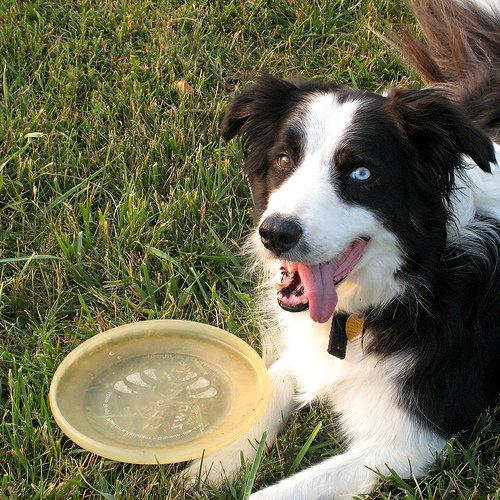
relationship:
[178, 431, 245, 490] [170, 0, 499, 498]
paw of dog